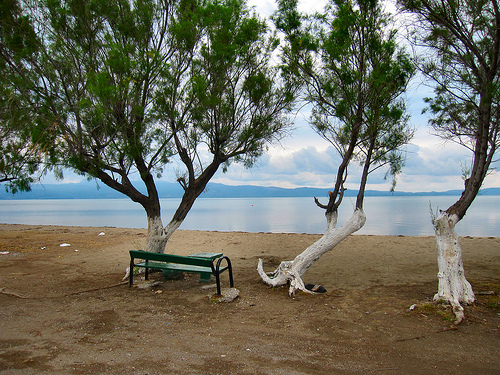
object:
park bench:
[117, 247, 238, 295]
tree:
[395, 0, 499, 322]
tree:
[258, 0, 419, 298]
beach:
[1, 222, 499, 374]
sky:
[0, 1, 499, 192]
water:
[1, 198, 497, 242]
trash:
[60, 243, 70, 246]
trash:
[98, 231, 104, 235]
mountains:
[2, 178, 499, 195]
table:
[188, 252, 223, 280]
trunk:
[426, 92, 496, 328]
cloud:
[194, 108, 498, 187]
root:
[257, 256, 286, 288]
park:
[18, 14, 491, 366]